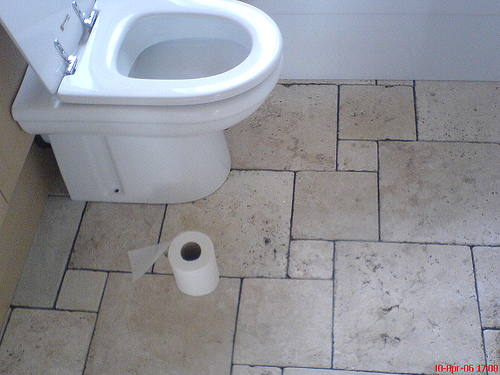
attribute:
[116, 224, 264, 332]
roll — toilet tissue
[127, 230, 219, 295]
roll — toilet tissue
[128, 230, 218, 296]
tissue — toilet tissue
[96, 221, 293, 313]
roll — toilet tissue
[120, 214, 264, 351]
tissue roll — toilet tissue